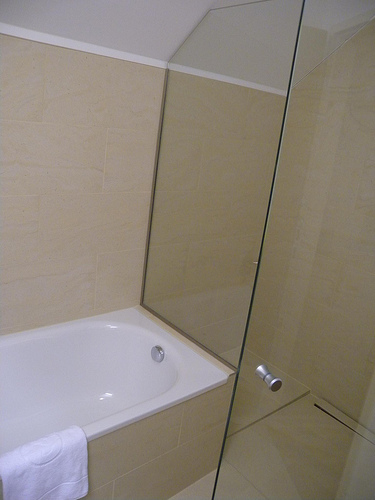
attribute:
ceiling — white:
[151, 13, 176, 36]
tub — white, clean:
[73, 382, 139, 412]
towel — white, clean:
[42, 432, 87, 459]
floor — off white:
[194, 482, 217, 490]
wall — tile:
[84, 90, 137, 105]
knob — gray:
[248, 357, 285, 395]